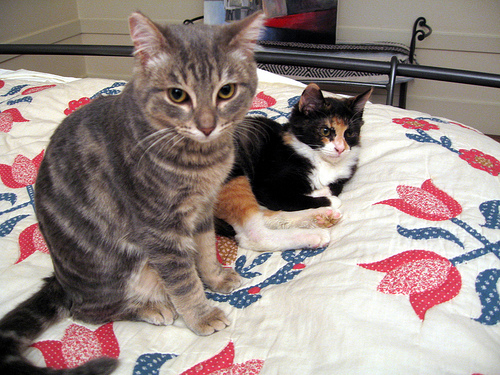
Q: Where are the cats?
A: On a bed.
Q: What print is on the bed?
A: Flowers.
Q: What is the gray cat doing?
A: Sitting on a bed.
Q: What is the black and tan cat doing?
A: Lying on a bed.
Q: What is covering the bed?
A: A blanket.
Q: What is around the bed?
A: Black railings.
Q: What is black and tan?
A: A cat.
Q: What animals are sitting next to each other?
A: Cats.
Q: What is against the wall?
A: A bench.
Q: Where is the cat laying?
A: Bed.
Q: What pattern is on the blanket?
A: Flower.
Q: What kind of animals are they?
A: Cats.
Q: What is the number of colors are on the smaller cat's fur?
A: 3.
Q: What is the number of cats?
A: 2.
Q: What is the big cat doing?
A: Sitting.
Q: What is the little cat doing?
A: Laying.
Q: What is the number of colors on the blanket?
A: 3.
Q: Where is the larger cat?
A: Left.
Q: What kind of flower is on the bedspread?
A: Tulip.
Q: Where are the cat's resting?
A: Bed.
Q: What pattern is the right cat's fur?
A: Calico.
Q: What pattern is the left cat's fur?
A: Striped.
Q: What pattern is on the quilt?
A: Tulips.